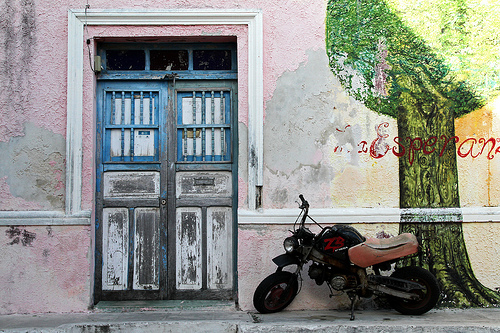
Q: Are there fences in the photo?
A: No, there are no fences.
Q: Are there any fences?
A: No, there are no fences.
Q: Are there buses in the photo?
A: No, there are no buses.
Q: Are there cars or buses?
A: No, there are no buses or cars.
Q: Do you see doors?
A: Yes, there is a door.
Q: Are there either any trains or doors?
A: Yes, there is a door.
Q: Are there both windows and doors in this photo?
A: Yes, there are both a door and a window.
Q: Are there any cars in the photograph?
A: No, there are no cars.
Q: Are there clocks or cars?
A: No, there are no cars or clocks.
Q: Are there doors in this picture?
A: Yes, there is a door.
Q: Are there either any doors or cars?
A: Yes, there is a door.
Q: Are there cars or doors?
A: Yes, there is a door.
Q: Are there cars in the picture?
A: No, there are no cars.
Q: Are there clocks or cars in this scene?
A: No, there are no cars or clocks.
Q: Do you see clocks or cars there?
A: No, there are no cars or clocks.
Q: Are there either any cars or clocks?
A: No, there are no cars or clocks.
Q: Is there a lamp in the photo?
A: No, there are no lamps.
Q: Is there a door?
A: Yes, there are doors.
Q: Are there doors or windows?
A: Yes, there are doors.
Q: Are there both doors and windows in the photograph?
A: Yes, there are both doors and windows.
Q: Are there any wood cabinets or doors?
A: Yes, there are wood doors.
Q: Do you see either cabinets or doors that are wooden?
A: Yes, the doors are wooden.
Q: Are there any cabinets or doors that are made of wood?
A: Yes, the doors are made of wood.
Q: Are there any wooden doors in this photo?
A: Yes, there are wood doors.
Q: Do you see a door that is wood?
A: Yes, there are wood doors.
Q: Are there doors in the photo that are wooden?
A: Yes, there are doors that are wooden.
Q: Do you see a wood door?
A: Yes, there are doors that are made of wood.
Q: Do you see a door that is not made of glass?
A: Yes, there are doors that are made of wood.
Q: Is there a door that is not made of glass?
A: Yes, there are doors that are made of wood.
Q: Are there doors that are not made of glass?
A: Yes, there are doors that are made of wood.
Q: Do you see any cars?
A: No, there are no cars.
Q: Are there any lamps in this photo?
A: No, there are no lamps.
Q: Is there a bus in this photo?
A: No, there are no buses.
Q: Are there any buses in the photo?
A: No, there are no buses.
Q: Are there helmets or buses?
A: No, there are no buses or helmets.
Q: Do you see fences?
A: No, there are no fences.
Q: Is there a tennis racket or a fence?
A: No, there are no fences or rackets.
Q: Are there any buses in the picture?
A: No, there are no buses.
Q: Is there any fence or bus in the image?
A: No, there are no buses or fences.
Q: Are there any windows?
A: Yes, there are windows.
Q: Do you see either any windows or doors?
A: Yes, there are windows.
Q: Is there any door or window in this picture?
A: Yes, there are windows.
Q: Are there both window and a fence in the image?
A: No, there are windows but no fences.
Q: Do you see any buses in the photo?
A: No, there are no buses.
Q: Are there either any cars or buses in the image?
A: No, there are no buses or cars.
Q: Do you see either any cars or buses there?
A: No, there are no buses or cars.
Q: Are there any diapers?
A: No, there are no diapers.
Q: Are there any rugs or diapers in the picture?
A: No, there are no diapers or rugs.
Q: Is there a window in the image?
A: Yes, there is a window.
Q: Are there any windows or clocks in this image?
A: Yes, there is a window.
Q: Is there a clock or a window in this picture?
A: Yes, there is a window.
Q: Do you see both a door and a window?
A: Yes, there are both a window and a door.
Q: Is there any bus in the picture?
A: No, there are no buses.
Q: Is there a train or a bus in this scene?
A: No, there are no buses or trains.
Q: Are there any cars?
A: No, there are no cars.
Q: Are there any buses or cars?
A: No, there are no cars or buses.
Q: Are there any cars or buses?
A: No, there are no cars or buses.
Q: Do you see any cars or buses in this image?
A: No, there are no cars or buses.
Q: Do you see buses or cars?
A: No, there are no cars or buses.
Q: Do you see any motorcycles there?
A: Yes, there is a motorcycle.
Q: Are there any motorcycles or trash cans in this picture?
A: Yes, there is a motorcycle.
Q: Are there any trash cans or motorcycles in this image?
A: Yes, there is a motorcycle.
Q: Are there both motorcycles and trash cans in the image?
A: No, there is a motorcycle but no trash cans.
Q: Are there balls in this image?
A: No, there are no balls.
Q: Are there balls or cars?
A: No, there are no balls or cars.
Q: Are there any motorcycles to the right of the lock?
A: Yes, there is a motorcycle to the right of the lock.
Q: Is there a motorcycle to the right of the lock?
A: Yes, there is a motorcycle to the right of the lock.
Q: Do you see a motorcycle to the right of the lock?
A: Yes, there is a motorcycle to the right of the lock.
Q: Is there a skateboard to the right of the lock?
A: No, there is a motorcycle to the right of the lock.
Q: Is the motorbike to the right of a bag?
A: No, the motorbike is to the right of the lock.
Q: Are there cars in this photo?
A: No, there are no cars.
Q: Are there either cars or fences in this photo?
A: No, there are no cars or fences.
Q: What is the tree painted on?
A: The tree is painted on the building.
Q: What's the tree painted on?
A: The tree is painted on the building.